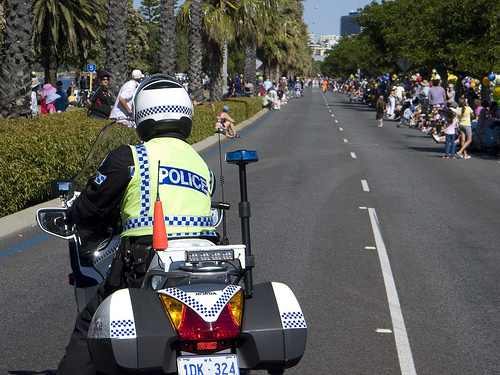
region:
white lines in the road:
[320, 101, 370, 190]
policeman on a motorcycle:
[36, 72, 291, 371]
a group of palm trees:
[180, 0, 305, 85]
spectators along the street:
[357, 67, 489, 156]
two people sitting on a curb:
[208, 102, 246, 142]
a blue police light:
[218, 142, 263, 197]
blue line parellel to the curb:
[0, 239, 53, 260]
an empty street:
[281, 95, 431, 361]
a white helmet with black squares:
[117, 65, 212, 140]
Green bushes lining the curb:
[0, 120, 82, 216]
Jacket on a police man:
[86, 120, 276, 283]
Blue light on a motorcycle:
[213, 143, 274, 260]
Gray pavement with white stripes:
[260, 114, 416, 286]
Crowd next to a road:
[338, 73, 493, 155]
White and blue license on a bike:
[173, 351, 261, 373]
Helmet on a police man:
[121, 70, 205, 136]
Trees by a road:
[109, 6, 315, 113]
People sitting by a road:
[218, 66, 305, 116]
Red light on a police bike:
[153, 284, 270, 358]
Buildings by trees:
[303, 8, 368, 83]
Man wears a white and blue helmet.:
[123, 74, 206, 136]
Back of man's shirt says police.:
[133, 144, 218, 213]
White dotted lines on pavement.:
[349, 154, 430, 371]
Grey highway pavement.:
[301, 164, 351, 295]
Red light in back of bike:
[158, 311, 258, 338]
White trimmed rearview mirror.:
[29, 202, 82, 240]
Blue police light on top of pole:
[216, 143, 263, 178]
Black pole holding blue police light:
[231, 168, 265, 290]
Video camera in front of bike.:
[50, 176, 80, 197]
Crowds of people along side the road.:
[342, 63, 497, 165]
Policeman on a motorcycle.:
[35, 73, 325, 373]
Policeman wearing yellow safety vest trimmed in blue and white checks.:
[118, 136, 240, 238]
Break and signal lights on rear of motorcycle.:
[154, 286, 261, 351]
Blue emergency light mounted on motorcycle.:
[222, 144, 268, 305]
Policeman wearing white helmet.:
[128, 76, 199, 141]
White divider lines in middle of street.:
[327, 101, 375, 208]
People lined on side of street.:
[340, 63, 497, 162]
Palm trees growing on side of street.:
[71, 1, 287, 102]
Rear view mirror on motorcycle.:
[33, 203, 79, 243]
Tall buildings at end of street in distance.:
[302, 7, 375, 74]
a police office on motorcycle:
[49, 41, 321, 356]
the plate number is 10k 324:
[157, 340, 266, 374]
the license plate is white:
[148, 318, 236, 365]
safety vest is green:
[43, 40, 274, 277]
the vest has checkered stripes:
[63, 43, 319, 325]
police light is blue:
[209, 116, 299, 206]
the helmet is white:
[100, 35, 267, 178]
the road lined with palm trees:
[141, 2, 362, 134]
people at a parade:
[307, 27, 474, 198]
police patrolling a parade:
[24, 9, 396, 352]